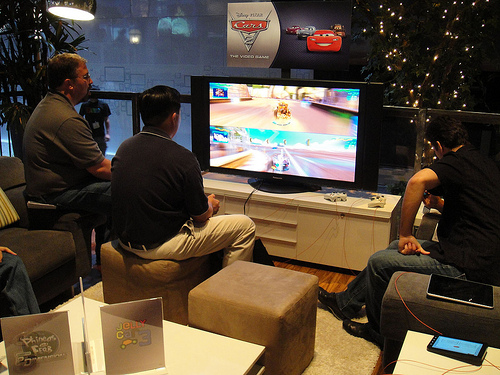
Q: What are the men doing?
A: Playing video games.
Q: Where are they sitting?
A: In a living room.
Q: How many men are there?
A: Three.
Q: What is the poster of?
A: Cars.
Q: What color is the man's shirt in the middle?
A: Black.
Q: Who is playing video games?
A: The men.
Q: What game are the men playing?
A: Mario Kart.